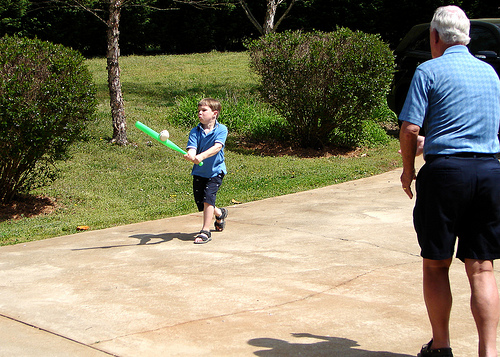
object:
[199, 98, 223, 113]
hair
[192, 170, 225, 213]
shorts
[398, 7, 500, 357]
man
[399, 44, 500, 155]
blue shirt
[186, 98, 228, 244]
boy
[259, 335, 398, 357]
shadow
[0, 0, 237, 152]
tree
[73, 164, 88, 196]
ground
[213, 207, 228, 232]
sandals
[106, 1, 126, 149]
tree trunk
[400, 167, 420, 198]
hand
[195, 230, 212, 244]
sandal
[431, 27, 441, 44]
ear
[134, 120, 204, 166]
baseball bat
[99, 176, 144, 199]
grass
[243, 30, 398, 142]
bush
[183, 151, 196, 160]
boy's hand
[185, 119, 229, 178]
shirt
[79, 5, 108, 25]
branch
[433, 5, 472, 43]
hair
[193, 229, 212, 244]
left foot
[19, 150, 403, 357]
driveway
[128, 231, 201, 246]
shadow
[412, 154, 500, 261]
blue shorts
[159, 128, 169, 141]
ball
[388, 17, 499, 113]
car